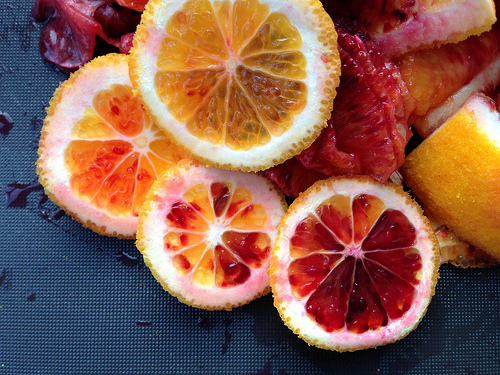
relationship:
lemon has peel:
[128, 1, 343, 173] [198, 147, 278, 171]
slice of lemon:
[236, 62, 319, 140] [128, 1, 343, 173]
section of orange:
[288, 222, 354, 263] [269, 178, 441, 353]